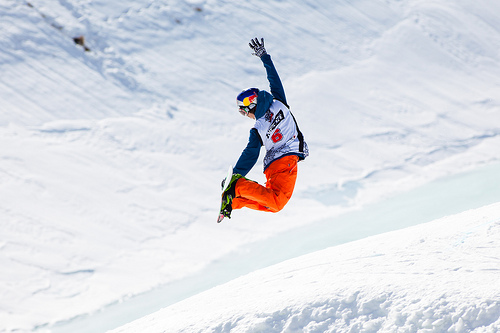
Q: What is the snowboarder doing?
A: Tricks.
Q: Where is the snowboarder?
A: In the air.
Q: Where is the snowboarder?
A: In the snow.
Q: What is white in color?
A: The snow.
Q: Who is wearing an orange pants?
A: The snowboarder.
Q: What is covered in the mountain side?
A: Snow.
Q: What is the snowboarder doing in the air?
A: Playing tricks.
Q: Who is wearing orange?
A: The man.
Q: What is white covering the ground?
A: Snow.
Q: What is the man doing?
A: Snowboarding.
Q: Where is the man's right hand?
A: In the air.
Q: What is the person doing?
A: A trick.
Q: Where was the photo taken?
A: The mountain.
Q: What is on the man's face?
A: Goggles.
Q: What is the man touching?
A: The board.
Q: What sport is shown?
A: Snowboarding.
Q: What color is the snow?
A: White.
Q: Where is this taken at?
A: Snowbank.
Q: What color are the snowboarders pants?
A: Orange.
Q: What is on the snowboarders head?
A: Goggles.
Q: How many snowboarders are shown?
A: 1.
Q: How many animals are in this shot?
A: 0.